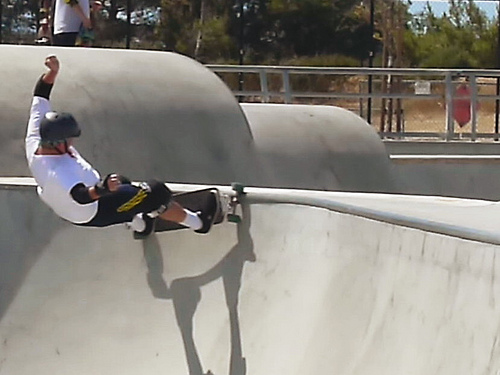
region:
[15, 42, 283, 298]
this is a person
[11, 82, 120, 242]
person wearing a white shirt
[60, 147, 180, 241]
man wearing black shorts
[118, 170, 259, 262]
the skateboard is black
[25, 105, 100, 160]
the helmet is black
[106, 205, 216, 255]
man wearing white socks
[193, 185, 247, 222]
metal portion of skateboard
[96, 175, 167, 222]
yellow portion on shorts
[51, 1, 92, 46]
a man standing on a concrete tube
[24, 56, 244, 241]
a man skateboarding in a pool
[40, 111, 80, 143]
a man's skateboard helmet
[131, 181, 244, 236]
a man's black skateboard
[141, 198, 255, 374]
shadow of a skateboarder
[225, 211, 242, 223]
a skateboard's right front wheel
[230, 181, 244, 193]
a skateboard's left front wheel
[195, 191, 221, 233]
a man's right foot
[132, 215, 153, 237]
a man's left foot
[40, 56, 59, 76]
a man's left hand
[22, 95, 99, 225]
white cotton tee shirt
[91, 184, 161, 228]
black and yellow pants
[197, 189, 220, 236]
white and black sneakers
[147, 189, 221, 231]
black and grey skate board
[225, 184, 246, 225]
grey tires on skate board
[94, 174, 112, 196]
black wrap on hand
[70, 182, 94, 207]
black wrap on elbow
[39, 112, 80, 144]
black plastic helmet on head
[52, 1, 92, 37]
white cotton tee shirt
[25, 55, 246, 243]
man riding on skate board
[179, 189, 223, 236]
Skater wearing white socks and black sneakers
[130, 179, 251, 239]
Black skateboard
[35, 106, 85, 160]
Man wearing black helmet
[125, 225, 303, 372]
Strange shadow from man skateboarding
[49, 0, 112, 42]
Guy in white t-shirt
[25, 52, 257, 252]
Guy skateboarding in park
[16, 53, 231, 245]
Skateboarding on the halfpipe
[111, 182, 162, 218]
Yellow strips on the man's black shorts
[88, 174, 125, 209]
Wearing black safety glove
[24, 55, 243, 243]
Man skateboarding at a skateboard park.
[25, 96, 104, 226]
Man wearing a white T-shirt.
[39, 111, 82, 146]
Man wearing a blue helmet.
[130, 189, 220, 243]
Man wearing black tennis shoes.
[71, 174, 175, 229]
Man wearing blue shorts with yellow stripe.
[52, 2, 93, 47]
Man walking on sidewalk.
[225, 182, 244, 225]
Skateboard wheels are green.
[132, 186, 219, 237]
Skateboard is black in color.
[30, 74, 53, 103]
Man is wearing black elbow protectors.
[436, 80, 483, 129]
There is an orange street sign sitting on the sidewalk.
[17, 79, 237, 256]
man on the skateboard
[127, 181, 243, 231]
skateboard on his feet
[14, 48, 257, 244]
man on a skateboard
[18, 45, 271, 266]
the man is sideways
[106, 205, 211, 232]
a pair of white sock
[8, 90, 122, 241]
man wearing a white shirt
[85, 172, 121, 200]
man wearing a wrist guard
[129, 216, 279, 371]
shadow on the pike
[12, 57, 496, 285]
man is on the edge of a pike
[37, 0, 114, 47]
person in the background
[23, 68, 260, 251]
person on a skateboard doing tricks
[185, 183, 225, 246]
person wearing black skateshoes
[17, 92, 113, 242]
guy wearing a white t-shirt